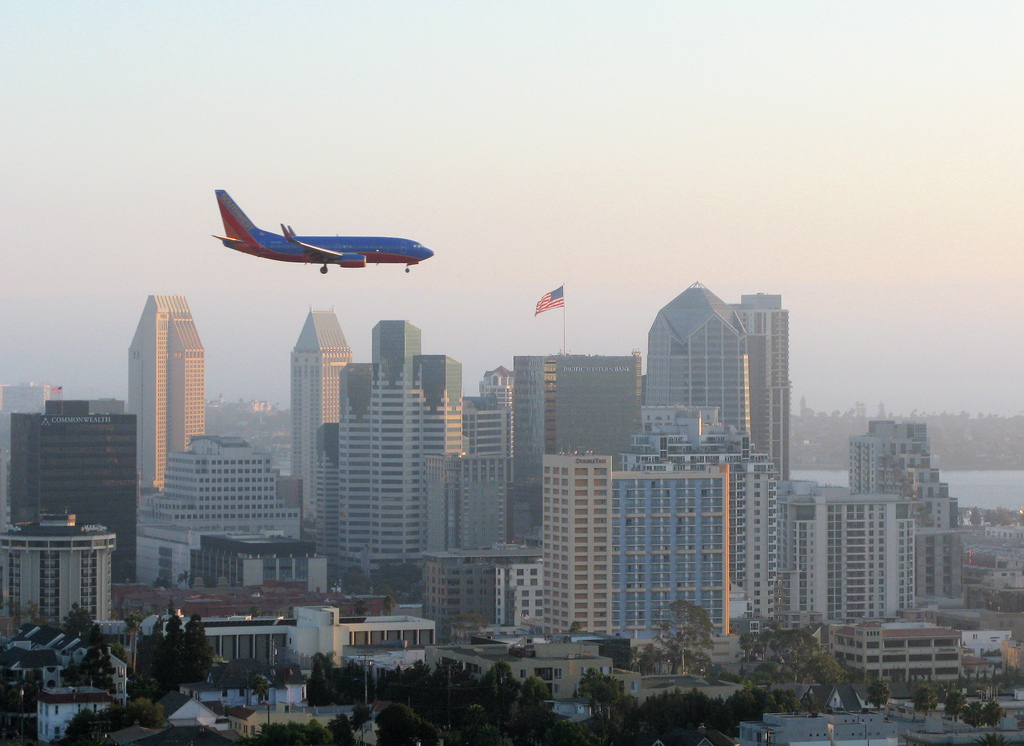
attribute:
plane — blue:
[214, 186, 438, 276]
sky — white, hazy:
[0, 2, 1022, 407]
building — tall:
[515, 352, 643, 552]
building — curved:
[641, 279, 750, 438]